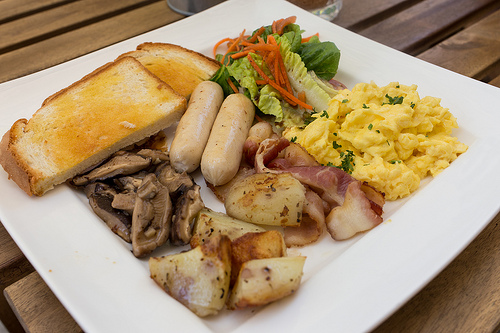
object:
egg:
[282, 80, 469, 201]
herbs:
[381, 94, 405, 105]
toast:
[0, 41, 222, 199]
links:
[168, 85, 235, 185]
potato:
[150, 245, 232, 318]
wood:
[356, 0, 494, 50]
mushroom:
[169, 182, 206, 243]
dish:
[0, 0, 499, 332]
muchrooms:
[71, 153, 151, 185]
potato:
[229, 254, 307, 309]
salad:
[208, 15, 341, 128]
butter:
[55, 104, 128, 135]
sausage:
[169, 80, 224, 174]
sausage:
[200, 93, 256, 187]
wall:
[234, 75, 309, 125]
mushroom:
[111, 172, 171, 257]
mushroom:
[89, 178, 133, 244]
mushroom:
[155, 163, 195, 193]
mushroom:
[137, 148, 170, 166]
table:
[0, 0, 499, 332]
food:
[0, 15, 469, 317]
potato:
[215, 167, 307, 226]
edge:
[0, 213, 101, 333]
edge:
[1, 286, 34, 333]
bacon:
[253, 137, 386, 240]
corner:
[228, 0, 313, 14]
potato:
[190, 206, 287, 285]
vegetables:
[230, 33, 332, 127]